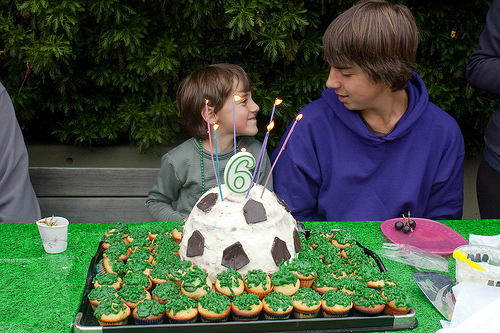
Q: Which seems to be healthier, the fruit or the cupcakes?
A: The fruit is healthier than the cupcakes.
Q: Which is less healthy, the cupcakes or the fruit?
A: The cupcakes is less healthy than the fruit.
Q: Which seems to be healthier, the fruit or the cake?
A: The fruit is healthier than the cake.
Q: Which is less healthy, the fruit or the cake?
A: The cake is less healthy than the fruit.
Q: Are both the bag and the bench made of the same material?
A: No, the bag is made of plastic and the bench is made of wood.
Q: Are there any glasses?
A: No, there are no glasses.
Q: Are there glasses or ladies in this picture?
A: No, there are no glasses or ladies.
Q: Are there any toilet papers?
A: No, there are no toilet papers.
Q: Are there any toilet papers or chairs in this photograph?
A: No, there are no toilet papers or chairs.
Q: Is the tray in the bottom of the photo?
A: Yes, the tray is in the bottom of the image.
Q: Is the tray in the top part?
A: No, the tray is in the bottom of the image.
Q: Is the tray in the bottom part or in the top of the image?
A: The tray is in the bottom of the image.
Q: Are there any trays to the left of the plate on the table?
A: Yes, there is a tray to the left of the plate.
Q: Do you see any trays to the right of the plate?
A: No, the tray is to the left of the plate.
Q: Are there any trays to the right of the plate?
A: No, the tray is to the left of the plate.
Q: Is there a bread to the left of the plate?
A: No, there is a tray to the left of the plate.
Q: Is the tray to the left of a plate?
A: Yes, the tray is to the left of a plate.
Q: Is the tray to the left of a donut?
A: No, the tray is to the left of a plate.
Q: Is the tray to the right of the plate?
A: No, the tray is to the left of the plate.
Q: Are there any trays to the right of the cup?
A: Yes, there is a tray to the right of the cup.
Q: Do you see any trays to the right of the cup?
A: Yes, there is a tray to the right of the cup.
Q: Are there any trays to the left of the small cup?
A: No, the tray is to the right of the cup.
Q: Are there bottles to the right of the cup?
A: No, there is a tray to the right of the cup.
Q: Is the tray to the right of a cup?
A: Yes, the tray is to the right of a cup.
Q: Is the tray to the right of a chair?
A: No, the tray is to the right of a cup.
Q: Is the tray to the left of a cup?
A: No, the tray is to the right of a cup.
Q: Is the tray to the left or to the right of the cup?
A: The tray is to the right of the cup.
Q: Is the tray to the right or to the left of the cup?
A: The tray is to the right of the cup.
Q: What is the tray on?
A: The tray is on the table.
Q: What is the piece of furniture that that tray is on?
A: The piece of furniture is a table.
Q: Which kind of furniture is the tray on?
A: The tray is on the table.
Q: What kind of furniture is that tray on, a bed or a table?
A: The tray is on a table.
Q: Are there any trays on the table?
A: Yes, there is a tray on the table.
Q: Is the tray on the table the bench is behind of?
A: Yes, the tray is on the table.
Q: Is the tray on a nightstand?
A: No, the tray is on the table.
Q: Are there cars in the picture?
A: No, there are no cars.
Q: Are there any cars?
A: No, there are no cars.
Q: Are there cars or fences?
A: No, there are no cars or fences.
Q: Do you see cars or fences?
A: No, there are no cars or fences.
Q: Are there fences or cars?
A: No, there are no cars or fences.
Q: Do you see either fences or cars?
A: No, there are no cars or fences.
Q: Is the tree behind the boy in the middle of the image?
A: Yes, the tree is behind the boy.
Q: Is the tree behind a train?
A: No, the tree is behind the boy.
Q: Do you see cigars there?
A: No, there are no cigars.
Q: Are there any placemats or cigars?
A: No, there are no cigars or placemats.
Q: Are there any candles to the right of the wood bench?
A: Yes, there is a candle to the right of the bench.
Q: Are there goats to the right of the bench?
A: No, there is a candle to the right of the bench.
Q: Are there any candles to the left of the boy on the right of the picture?
A: Yes, there is a candle to the left of the boy.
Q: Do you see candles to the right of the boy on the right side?
A: No, the candle is to the left of the boy.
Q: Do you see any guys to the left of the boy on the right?
A: No, there is a candle to the left of the boy.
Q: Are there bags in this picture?
A: Yes, there is a bag.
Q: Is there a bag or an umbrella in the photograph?
A: Yes, there is a bag.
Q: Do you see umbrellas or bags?
A: Yes, there is a bag.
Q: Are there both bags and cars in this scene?
A: No, there is a bag but no cars.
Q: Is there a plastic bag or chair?
A: Yes, there is a plastic bag.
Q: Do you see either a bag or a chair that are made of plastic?
A: Yes, the bag is made of plastic.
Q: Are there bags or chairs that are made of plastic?
A: Yes, the bag is made of plastic.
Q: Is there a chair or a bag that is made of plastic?
A: Yes, the bag is made of plastic.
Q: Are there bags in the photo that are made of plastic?
A: Yes, there is a bag that is made of plastic.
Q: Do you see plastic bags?
A: Yes, there is a bag that is made of plastic.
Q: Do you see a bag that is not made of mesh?
A: Yes, there is a bag that is made of plastic.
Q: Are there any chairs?
A: No, there are no chairs.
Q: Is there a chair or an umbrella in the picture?
A: No, there are no chairs or umbrellas.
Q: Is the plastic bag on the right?
A: Yes, the bag is on the right of the image.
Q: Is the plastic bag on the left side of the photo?
A: No, the bag is on the right of the image.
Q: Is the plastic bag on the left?
A: No, the bag is on the right of the image.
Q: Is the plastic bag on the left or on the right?
A: The bag is on the right of the image.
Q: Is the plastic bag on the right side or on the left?
A: The bag is on the right of the image.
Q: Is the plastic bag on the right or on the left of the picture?
A: The bag is on the right of the image.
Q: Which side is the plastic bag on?
A: The bag is on the right of the image.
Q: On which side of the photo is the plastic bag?
A: The bag is on the right of the image.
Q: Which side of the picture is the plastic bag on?
A: The bag is on the right of the image.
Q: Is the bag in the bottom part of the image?
A: Yes, the bag is in the bottom of the image.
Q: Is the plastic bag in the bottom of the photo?
A: Yes, the bag is in the bottom of the image.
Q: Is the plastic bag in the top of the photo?
A: No, the bag is in the bottom of the image.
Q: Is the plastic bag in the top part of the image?
A: No, the bag is in the bottom of the image.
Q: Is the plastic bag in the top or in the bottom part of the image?
A: The bag is in the bottom of the image.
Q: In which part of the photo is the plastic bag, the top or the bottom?
A: The bag is in the bottom of the image.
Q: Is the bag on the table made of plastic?
A: Yes, the bag is made of plastic.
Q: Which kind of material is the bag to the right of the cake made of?
A: The bag is made of plastic.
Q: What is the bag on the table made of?
A: The bag is made of plastic.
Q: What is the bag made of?
A: The bag is made of plastic.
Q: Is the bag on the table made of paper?
A: No, the bag is made of plastic.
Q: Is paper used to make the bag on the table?
A: No, the bag is made of plastic.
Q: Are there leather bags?
A: No, there is a bag but it is made of plastic.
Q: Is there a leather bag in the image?
A: No, there is a bag but it is made of plastic.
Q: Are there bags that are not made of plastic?
A: No, there is a bag but it is made of plastic.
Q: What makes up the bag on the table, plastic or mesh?
A: The bag is made of plastic.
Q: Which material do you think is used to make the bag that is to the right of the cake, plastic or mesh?
A: The bag is made of plastic.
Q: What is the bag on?
A: The bag is on the table.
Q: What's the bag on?
A: The bag is on the table.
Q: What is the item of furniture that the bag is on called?
A: The piece of furniture is a table.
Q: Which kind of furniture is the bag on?
A: The bag is on the table.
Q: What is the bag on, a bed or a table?
A: The bag is on a table.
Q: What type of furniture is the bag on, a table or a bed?
A: The bag is on a table.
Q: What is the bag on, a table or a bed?
A: The bag is on a table.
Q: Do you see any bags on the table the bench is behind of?
A: Yes, there is a bag on the table.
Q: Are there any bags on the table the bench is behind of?
A: Yes, there is a bag on the table.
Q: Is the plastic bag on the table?
A: Yes, the bag is on the table.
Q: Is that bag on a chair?
A: No, the bag is on the table.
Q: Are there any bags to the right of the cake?
A: Yes, there is a bag to the right of the cake.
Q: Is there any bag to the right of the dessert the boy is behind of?
A: Yes, there is a bag to the right of the cake.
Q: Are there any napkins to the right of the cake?
A: No, there is a bag to the right of the cake.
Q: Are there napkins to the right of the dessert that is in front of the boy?
A: No, there is a bag to the right of the cake.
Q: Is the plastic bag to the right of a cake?
A: Yes, the bag is to the right of a cake.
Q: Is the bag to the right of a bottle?
A: No, the bag is to the right of a cake.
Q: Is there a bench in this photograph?
A: Yes, there is a bench.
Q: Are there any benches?
A: Yes, there is a bench.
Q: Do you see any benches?
A: Yes, there is a bench.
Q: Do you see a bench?
A: Yes, there is a bench.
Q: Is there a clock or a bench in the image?
A: Yes, there is a bench.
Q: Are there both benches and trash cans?
A: No, there is a bench but no trash cans.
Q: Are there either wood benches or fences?
A: Yes, there is a wood bench.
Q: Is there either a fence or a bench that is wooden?
A: Yes, the bench is wooden.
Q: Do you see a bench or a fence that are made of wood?
A: Yes, the bench is made of wood.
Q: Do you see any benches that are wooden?
A: Yes, there is a wood bench.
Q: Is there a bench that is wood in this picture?
A: Yes, there is a wood bench.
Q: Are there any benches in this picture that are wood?
A: Yes, there is a wood bench.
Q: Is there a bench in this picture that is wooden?
A: Yes, there is a bench that is wooden.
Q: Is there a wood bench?
A: Yes, there is a bench that is made of wood.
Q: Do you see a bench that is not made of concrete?
A: Yes, there is a bench that is made of wood.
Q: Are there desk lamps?
A: No, there are no desk lamps.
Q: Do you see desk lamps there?
A: No, there are no desk lamps.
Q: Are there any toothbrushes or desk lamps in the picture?
A: No, there are no desk lamps or toothbrushes.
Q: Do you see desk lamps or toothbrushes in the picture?
A: No, there are no desk lamps or toothbrushes.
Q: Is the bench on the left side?
A: Yes, the bench is on the left of the image.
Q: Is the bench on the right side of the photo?
A: No, the bench is on the left of the image.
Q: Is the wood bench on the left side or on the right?
A: The bench is on the left of the image.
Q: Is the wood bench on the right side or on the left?
A: The bench is on the left of the image.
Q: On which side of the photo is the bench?
A: The bench is on the left of the image.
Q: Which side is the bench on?
A: The bench is on the left of the image.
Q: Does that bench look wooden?
A: Yes, the bench is wooden.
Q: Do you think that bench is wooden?
A: Yes, the bench is wooden.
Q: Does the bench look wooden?
A: Yes, the bench is wooden.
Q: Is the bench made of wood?
A: Yes, the bench is made of wood.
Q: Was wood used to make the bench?
A: Yes, the bench is made of wood.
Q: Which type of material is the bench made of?
A: The bench is made of wood.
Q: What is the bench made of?
A: The bench is made of wood.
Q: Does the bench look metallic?
A: No, the bench is wooden.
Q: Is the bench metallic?
A: No, the bench is wooden.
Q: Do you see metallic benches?
A: No, there is a bench but it is wooden.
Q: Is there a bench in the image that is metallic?
A: No, there is a bench but it is wooden.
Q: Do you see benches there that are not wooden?
A: No, there is a bench but it is wooden.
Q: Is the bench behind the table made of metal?
A: No, the bench is made of wood.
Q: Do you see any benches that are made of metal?
A: No, there is a bench but it is made of wood.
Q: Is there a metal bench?
A: No, there is a bench but it is made of wood.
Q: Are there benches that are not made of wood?
A: No, there is a bench but it is made of wood.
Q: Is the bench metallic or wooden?
A: The bench is wooden.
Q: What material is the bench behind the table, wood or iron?
A: The bench is made of wood.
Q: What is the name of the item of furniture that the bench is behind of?
A: The piece of furniture is a table.